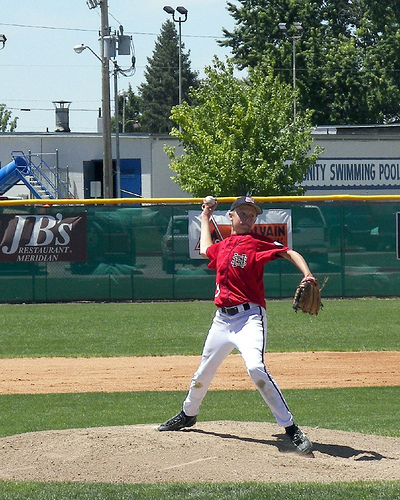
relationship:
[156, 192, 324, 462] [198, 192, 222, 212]
boy playing baseball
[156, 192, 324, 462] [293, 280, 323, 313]
boy wearing glove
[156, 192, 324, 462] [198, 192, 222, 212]
boy throwing baseball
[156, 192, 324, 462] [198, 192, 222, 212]
boy holding baseball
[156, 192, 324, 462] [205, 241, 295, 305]
boy wearing uniform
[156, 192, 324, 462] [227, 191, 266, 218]
boy wearing cap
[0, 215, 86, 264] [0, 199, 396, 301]
sign on fence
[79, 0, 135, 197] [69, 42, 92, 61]
power pole light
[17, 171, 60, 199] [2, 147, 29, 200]
stairs blue waterslide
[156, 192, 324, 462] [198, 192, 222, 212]
boy pitching baseball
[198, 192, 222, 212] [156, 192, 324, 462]
baseball uniform boy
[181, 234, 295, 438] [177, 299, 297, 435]
uniform white pants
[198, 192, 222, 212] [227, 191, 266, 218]
baseball uniform cap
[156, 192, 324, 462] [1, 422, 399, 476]
pitcher's mound sand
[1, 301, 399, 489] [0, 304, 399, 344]
field green grass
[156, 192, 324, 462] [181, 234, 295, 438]
boy baseball uniform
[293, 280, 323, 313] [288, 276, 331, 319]
glove on hand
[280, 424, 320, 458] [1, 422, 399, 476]
cleat in sand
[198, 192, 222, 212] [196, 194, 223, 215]
baseball in hand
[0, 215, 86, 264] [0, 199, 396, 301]
banner on fence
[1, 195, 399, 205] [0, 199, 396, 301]
pad on fence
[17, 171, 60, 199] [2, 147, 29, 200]
stairs to slide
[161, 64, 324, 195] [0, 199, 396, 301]
tree behind fence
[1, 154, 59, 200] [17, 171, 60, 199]
blue slide stairs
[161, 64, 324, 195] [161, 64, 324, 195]
tree green leaves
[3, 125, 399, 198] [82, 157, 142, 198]
building open door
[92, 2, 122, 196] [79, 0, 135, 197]
brown electrical pole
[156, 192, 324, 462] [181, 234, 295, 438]
boy wearing uniform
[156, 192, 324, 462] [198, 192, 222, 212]
player holding ball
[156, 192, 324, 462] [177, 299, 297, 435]
player white pants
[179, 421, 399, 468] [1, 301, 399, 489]
shadow on ground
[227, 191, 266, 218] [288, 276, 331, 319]
hat on hand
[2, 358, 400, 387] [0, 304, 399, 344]
soil green grass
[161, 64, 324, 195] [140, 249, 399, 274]
tree on road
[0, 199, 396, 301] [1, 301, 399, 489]
fenced baseball field